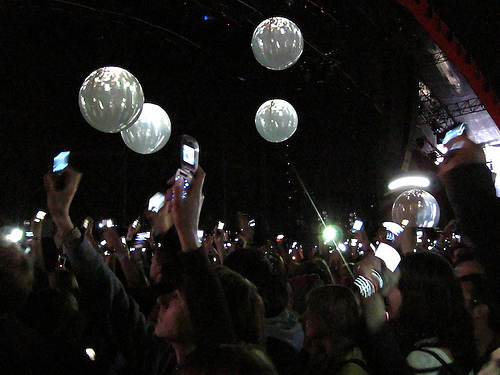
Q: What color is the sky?
A: Black.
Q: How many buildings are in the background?
A: 1.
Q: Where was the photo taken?
A: At a concert.